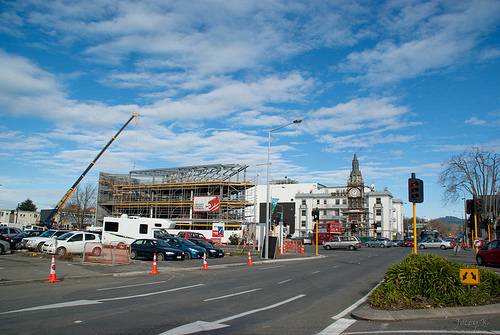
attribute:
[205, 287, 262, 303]
line — white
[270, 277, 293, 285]
line — white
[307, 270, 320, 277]
line — white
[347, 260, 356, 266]
line — white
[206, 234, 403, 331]
street — Paved 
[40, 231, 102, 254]
car — white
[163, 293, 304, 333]
arrow — white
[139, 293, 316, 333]
arrow — white 